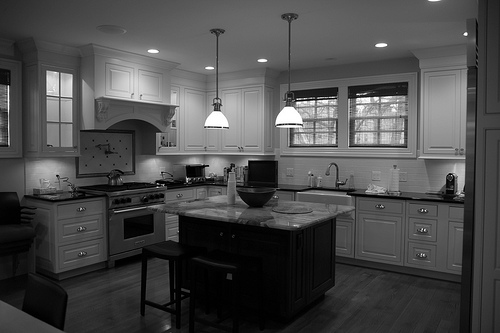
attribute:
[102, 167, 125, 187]
kettle — stainless steel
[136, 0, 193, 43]
ceiling — white, painted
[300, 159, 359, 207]
sink — white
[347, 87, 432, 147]
window — glass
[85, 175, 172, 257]
range — silver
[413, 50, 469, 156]
cupboard — overhead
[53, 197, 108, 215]
top drawer — white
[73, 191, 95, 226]
knob — silver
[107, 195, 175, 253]
oven — stainless steel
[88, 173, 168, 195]
stovetop — stainless steel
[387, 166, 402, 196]
towels — paper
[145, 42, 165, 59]
light — round, white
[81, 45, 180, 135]
stove fan — overhead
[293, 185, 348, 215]
sink — white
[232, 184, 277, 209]
large bowl — dark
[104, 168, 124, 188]
kettle — silver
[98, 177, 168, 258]
stove — stainless steel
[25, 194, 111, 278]
cabinet — white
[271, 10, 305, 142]
light — pendant, hanging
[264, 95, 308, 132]
light — on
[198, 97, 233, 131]
light — on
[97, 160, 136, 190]
kettle — silver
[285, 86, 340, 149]
window — glass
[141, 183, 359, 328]
island — marble